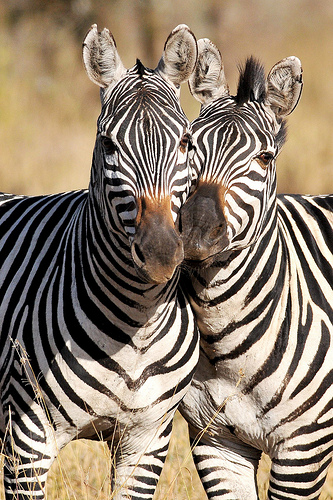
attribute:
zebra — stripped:
[0, 21, 196, 498]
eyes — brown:
[94, 126, 189, 155]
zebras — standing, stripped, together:
[0, 23, 331, 496]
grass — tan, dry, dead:
[64, 447, 192, 498]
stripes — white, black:
[0, 71, 332, 498]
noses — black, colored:
[127, 188, 233, 282]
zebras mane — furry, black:
[132, 54, 274, 104]